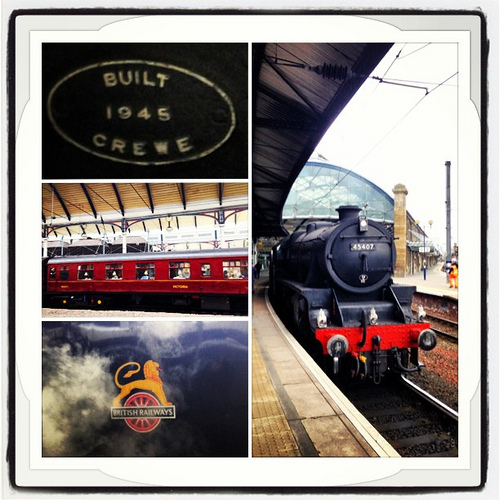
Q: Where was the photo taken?
A: It was taken at the station.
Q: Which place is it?
A: It is a station.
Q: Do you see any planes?
A: No, there are no planes.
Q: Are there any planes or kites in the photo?
A: No, there are no planes or kites.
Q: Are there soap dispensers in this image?
A: No, there are no soap dispensers.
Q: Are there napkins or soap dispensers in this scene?
A: No, there are no soap dispensers or napkins.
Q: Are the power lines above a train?
A: Yes, the power lines are above a train.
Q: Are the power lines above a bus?
A: No, the power lines are above a train.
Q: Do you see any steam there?
A: Yes, there is steam.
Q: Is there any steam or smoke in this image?
A: Yes, there is steam.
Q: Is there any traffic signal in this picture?
A: No, there are no traffic lights.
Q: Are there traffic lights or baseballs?
A: No, there are no traffic lights or baseballs.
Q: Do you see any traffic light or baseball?
A: No, there are no traffic lights or baseballs.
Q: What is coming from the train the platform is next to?
A: The steam is coming from the train.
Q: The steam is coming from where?
A: The steam is coming from the train.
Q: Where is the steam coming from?
A: The steam is coming from the train.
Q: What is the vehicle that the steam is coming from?
A: The vehicle is a train.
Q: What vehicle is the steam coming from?
A: The steam is coming from the train.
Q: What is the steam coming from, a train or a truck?
A: The steam is coming from a train.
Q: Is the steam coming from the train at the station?
A: Yes, the steam is coming from the train.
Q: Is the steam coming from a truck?
A: No, the steam is coming from the train.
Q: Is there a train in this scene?
A: Yes, there is a train.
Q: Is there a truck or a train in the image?
A: Yes, there is a train.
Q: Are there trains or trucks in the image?
A: Yes, there is a train.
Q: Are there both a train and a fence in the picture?
A: No, there is a train but no fences.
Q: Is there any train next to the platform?
A: Yes, there is a train next to the platform.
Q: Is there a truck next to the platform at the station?
A: No, there is a train next to the platform.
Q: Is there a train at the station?
A: Yes, there is a train at the station.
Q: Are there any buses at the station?
A: No, there is a train at the station.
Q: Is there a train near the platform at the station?
A: Yes, there is a train near the platform.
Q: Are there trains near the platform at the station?
A: Yes, there is a train near the platform.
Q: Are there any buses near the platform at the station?
A: No, there is a train near the platform.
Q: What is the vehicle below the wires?
A: The vehicle is a train.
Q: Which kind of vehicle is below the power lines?
A: The vehicle is a train.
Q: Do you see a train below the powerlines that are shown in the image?
A: Yes, there is a train below the powerlines.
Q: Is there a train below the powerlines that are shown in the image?
A: Yes, there is a train below the powerlines.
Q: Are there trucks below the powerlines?
A: No, there is a train below the powerlines.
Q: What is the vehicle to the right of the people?
A: The vehicle is a train.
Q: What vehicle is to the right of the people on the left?
A: The vehicle is a train.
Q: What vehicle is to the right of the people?
A: The vehicle is a train.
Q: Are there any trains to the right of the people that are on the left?
A: Yes, there is a train to the right of the people.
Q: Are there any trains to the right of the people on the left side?
A: Yes, there is a train to the right of the people.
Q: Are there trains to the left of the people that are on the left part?
A: No, the train is to the right of the people.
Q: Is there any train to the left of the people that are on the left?
A: No, the train is to the right of the people.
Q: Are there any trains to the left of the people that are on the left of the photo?
A: No, the train is to the right of the people.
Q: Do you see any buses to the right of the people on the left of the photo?
A: No, there is a train to the right of the people.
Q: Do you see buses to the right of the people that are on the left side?
A: No, there is a train to the right of the people.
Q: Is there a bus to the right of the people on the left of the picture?
A: No, there is a train to the right of the people.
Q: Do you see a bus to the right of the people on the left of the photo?
A: No, there is a train to the right of the people.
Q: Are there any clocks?
A: No, there are no clocks.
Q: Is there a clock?
A: No, there are no clocks.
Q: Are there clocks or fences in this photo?
A: No, there are no clocks or fences.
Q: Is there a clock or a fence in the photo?
A: No, there are no clocks or fences.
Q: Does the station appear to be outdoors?
A: Yes, the station is outdoors.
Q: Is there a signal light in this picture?
A: No, there are no traffic lights.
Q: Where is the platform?
A: The platform is at the station.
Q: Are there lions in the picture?
A: Yes, there is a lion.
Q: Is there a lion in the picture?
A: Yes, there is a lion.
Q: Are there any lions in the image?
A: Yes, there is a lion.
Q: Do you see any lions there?
A: Yes, there is a lion.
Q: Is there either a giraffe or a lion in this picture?
A: Yes, there is a lion.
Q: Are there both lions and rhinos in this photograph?
A: No, there is a lion but no rhinos.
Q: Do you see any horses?
A: No, there are no horses.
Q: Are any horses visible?
A: No, there are no horses.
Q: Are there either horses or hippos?
A: No, there are no horses or hippos.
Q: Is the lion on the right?
A: No, the lion is on the left of the image.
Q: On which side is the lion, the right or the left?
A: The lion is on the left of the image.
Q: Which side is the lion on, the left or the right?
A: The lion is on the left of the image.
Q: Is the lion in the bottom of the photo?
A: Yes, the lion is in the bottom of the image.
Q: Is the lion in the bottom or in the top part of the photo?
A: The lion is in the bottom of the image.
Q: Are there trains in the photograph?
A: Yes, there is a train.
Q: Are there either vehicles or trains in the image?
A: Yes, there is a train.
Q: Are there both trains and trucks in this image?
A: No, there is a train but no trucks.